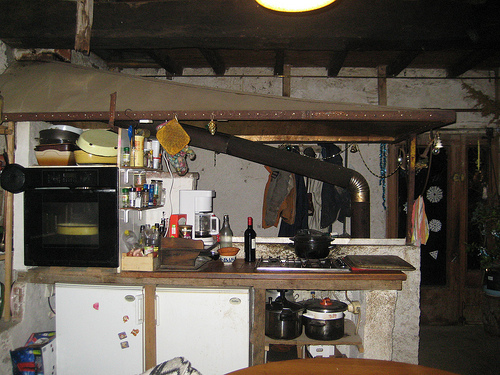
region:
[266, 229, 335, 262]
A pot on the burner.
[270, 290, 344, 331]
Pots under the cabinet.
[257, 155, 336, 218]
Jackets hanging from the wall.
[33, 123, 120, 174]
Pots on top of the microwave.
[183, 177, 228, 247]
A white coffee maker on the counter.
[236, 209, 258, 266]
A bottle of wine next to the stove.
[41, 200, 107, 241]
A pan in the microwave oven.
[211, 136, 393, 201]
A long pipe in the kitchen.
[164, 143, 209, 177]
A glove hanging from the canopy.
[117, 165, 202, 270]
The kitchen is junky.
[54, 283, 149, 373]
White door with stickers on it.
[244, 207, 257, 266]
Dark wine bottle with red top.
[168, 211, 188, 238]
Orange box near coffee maker.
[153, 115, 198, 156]
Dirty yellow square potholder.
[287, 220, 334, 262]
Black top with lid on stove top.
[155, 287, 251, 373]
Small white door without any stickers.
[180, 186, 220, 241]
White coffeemaker on counter.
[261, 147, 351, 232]
A bunch of coats hung on the wall.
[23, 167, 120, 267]
Black oven with yellow pan in it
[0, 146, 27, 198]
Small cast iron pan hung near oven.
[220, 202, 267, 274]
Bottles on counter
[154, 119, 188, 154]
Yellow oven mitt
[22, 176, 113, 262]
Black microwave is shiny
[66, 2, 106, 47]
Brown beam of roof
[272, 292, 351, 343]
Two pots on shelf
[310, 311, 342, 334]
These pots are stacked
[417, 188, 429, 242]
Towel hanging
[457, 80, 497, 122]
Part of Christmas tree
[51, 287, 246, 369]
Two white fridges beside each other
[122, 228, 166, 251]
Several empty bottles in a box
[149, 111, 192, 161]
yellow pt holder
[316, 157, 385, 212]
bend in a pipe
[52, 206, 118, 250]
yellow pan in microwave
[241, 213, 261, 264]
bottle with red top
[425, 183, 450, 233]
snowflakes on the door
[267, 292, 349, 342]
pots on a shelf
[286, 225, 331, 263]
pot on the stove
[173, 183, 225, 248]
coffee pot on the counter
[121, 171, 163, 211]
spices on a shelf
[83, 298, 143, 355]
stickers on a cabinet door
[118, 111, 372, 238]
Long dark colored pipe going through the room to the right then down to the floor.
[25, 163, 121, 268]
Black oven on top of a counter.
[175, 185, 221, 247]
White coffee maker with coffee pot.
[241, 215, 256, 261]
Black bottlle of wine with a red top.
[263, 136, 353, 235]
Assorted coats hanging behind a big pipe.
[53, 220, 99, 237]
A yellow pan inside a black oven.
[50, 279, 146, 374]
A small white fridge under the black oven.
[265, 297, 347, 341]
Two large pots with lids under the counter.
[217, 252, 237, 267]
A small white and blue bowl on the wood counter top.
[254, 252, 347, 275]
A silver stove top with black burners.